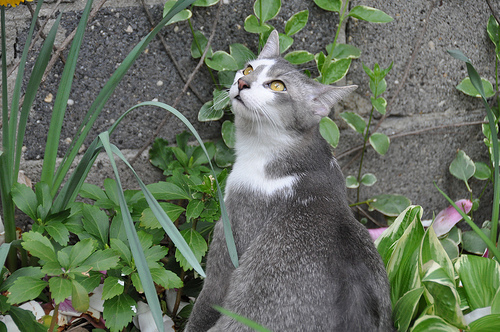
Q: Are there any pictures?
A: No, there are no pictures.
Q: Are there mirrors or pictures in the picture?
A: No, there are no pictures or mirrors.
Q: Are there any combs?
A: No, there are no combs.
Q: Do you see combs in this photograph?
A: No, there are no combs.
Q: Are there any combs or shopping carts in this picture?
A: No, there are no combs or shopping carts.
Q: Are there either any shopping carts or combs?
A: No, there are no combs or shopping carts.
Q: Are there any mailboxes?
A: No, there are no mailboxes.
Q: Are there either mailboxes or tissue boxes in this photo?
A: No, there are no mailboxes or tissue boxes.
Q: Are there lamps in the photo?
A: No, there are no lamps.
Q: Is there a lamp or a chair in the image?
A: No, there are no lamps or chairs.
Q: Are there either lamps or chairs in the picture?
A: No, there are no lamps or chairs.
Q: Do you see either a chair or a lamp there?
A: No, there are no lamps or chairs.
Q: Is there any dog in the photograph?
A: No, there are no dogs.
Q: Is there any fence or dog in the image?
A: No, there are no dogs or fences.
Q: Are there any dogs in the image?
A: No, there are no dogs.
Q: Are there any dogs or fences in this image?
A: No, there are no dogs or fences.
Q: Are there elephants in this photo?
A: No, there are no elephants.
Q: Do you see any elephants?
A: No, there are no elephants.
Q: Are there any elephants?
A: No, there are no elephants.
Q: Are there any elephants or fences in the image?
A: No, there are no elephants or fences.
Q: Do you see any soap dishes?
A: No, there are no soap dishes.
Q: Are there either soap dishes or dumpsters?
A: No, there are no soap dishes or dumpsters.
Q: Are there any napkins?
A: No, there are no napkins.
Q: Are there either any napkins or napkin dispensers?
A: No, there are no napkins or napkin dispensers.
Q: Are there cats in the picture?
A: Yes, there is a cat.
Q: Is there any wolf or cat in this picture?
A: Yes, there is a cat.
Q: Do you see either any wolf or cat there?
A: Yes, there is a cat.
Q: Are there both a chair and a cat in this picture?
A: No, there is a cat but no chairs.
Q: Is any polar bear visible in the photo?
A: No, there are no polar bears.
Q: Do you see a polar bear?
A: No, there are no polar bears.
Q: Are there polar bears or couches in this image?
A: No, there are no polar bears or couches.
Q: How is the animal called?
A: The animal is a cat.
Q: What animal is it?
A: The animal is a cat.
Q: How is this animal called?
A: This is a cat.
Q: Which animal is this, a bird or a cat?
A: This is a cat.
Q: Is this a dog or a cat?
A: This is a cat.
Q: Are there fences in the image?
A: No, there are no fences.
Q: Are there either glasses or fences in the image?
A: No, there are no fences or glasses.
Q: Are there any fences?
A: No, there are no fences.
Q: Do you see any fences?
A: No, there are no fences.